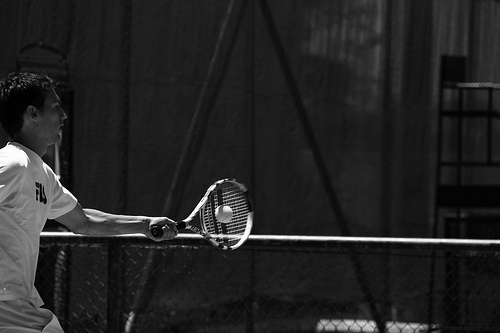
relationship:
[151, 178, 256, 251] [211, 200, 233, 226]
racket hitting ball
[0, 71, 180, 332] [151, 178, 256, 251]
man holding racket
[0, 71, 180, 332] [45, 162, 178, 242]
man has arm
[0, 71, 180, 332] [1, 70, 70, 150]
man has head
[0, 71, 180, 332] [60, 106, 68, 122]
man has nose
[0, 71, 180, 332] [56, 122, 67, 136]
man has mouth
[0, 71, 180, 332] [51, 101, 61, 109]
man has eye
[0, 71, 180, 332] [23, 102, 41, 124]
man has ear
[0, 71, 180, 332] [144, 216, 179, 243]
man has hand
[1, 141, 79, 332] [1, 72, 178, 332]
shirt on player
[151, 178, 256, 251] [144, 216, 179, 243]
racket in hand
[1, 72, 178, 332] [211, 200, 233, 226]
player swings at ball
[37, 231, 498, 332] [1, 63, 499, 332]
net across court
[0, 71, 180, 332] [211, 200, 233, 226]
man hitting ball